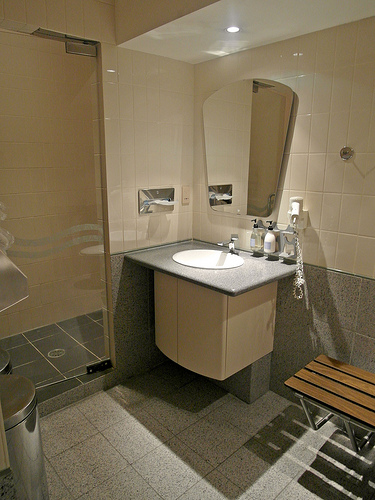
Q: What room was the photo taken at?
A: It was taken at the bathroom.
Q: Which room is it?
A: It is a bathroom.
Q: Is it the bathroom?
A: Yes, it is the bathroom.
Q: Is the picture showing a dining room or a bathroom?
A: It is showing a bathroom.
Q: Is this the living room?
A: No, it is the bathroom.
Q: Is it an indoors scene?
A: Yes, it is indoors.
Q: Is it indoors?
A: Yes, it is indoors.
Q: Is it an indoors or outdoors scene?
A: It is indoors.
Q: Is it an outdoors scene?
A: No, it is indoors.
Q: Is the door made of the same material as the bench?
A: No, the door is made of glass and the bench is made of wood.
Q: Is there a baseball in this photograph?
A: No, there are no baseballs.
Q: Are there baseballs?
A: No, there are no baseballs.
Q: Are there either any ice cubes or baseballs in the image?
A: No, there are no baseballs or ice cubes.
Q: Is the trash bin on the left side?
A: Yes, the trash bin is on the left of the image.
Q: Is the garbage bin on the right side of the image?
A: No, the garbage bin is on the left of the image.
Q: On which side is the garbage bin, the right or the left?
A: The garbage bin is on the left of the image.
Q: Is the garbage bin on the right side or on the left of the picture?
A: The garbage bin is on the left of the image.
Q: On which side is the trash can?
A: The trash can is on the left of the image.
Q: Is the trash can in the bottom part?
A: Yes, the trash can is in the bottom of the image.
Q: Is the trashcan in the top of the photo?
A: No, the trashcan is in the bottom of the image.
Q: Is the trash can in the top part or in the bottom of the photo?
A: The trash can is in the bottom of the image.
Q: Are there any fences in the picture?
A: No, there are no fences.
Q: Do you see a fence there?
A: No, there are no fences.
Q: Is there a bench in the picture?
A: Yes, there is a bench.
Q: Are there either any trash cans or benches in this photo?
A: Yes, there is a bench.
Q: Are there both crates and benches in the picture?
A: No, there is a bench but no crates.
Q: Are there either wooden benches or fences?
A: Yes, there is a wood bench.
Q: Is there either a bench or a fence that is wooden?
A: Yes, the bench is wooden.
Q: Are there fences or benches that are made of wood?
A: Yes, the bench is made of wood.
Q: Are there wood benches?
A: Yes, there is a bench that is made of wood.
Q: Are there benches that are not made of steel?
A: Yes, there is a bench that is made of wood.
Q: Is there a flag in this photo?
A: No, there are no flags.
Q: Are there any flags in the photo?
A: No, there are no flags.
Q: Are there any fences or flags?
A: No, there are no flags or fences.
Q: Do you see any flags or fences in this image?
A: No, there are no flags or fences.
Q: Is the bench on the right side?
A: Yes, the bench is on the right of the image.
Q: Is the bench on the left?
A: No, the bench is on the right of the image.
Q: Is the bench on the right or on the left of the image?
A: The bench is on the right of the image.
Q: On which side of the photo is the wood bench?
A: The bench is on the right of the image.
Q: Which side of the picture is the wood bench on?
A: The bench is on the right of the image.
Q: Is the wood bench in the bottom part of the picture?
A: Yes, the bench is in the bottom of the image.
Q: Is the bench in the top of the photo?
A: No, the bench is in the bottom of the image.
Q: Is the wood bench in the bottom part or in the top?
A: The bench is in the bottom of the image.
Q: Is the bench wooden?
A: Yes, the bench is wooden.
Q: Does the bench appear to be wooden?
A: Yes, the bench is wooden.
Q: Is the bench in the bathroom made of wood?
A: Yes, the bench is made of wood.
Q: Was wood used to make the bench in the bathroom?
A: Yes, the bench is made of wood.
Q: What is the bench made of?
A: The bench is made of wood.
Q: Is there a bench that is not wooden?
A: No, there is a bench but it is wooden.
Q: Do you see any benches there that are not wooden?
A: No, there is a bench but it is wooden.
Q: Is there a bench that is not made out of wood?
A: No, there is a bench but it is made of wood.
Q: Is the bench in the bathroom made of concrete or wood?
A: The bench is made of wood.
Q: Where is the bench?
A: The bench is in the bathroom.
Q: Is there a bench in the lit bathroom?
A: Yes, there is a bench in the bathroom.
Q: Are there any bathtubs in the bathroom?
A: No, there is a bench in the bathroom.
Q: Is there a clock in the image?
A: No, there are no clocks.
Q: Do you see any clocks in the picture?
A: No, there are no clocks.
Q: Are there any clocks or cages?
A: No, there are no clocks or cages.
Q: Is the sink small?
A: Yes, the sink is small.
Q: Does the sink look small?
A: Yes, the sink is small.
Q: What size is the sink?
A: The sink is small.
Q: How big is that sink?
A: The sink is small.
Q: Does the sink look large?
A: No, the sink is small.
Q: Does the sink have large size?
A: No, the sink is small.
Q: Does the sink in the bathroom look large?
A: No, the sink is small.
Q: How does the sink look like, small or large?
A: The sink is small.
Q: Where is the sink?
A: The sink is in the bathroom.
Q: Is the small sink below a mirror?
A: Yes, the sink is below a mirror.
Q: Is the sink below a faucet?
A: No, the sink is below a mirror.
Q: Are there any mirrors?
A: Yes, there is a mirror.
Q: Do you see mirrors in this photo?
A: Yes, there is a mirror.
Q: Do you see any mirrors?
A: Yes, there is a mirror.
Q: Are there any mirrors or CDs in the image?
A: Yes, there is a mirror.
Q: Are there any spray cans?
A: No, there are no spray cans.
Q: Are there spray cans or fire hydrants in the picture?
A: No, there are no spray cans or fire hydrants.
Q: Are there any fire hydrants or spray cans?
A: No, there are no spray cans or fire hydrants.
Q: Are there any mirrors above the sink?
A: Yes, there is a mirror above the sink.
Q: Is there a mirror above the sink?
A: Yes, there is a mirror above the sink.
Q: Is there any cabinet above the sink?
A: No, there is a mirror above the sink.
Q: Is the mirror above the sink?
A: Yes, the mirror is above the sink.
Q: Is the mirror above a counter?
A: No, the mirror is above the sink.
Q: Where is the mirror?
A: The mirror is in the bathroom.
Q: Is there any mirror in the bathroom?
A: Yes, there is a mirror in the bathroom.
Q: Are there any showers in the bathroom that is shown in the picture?
A: No, there is a mirror in the bathroom.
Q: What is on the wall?
A: The mirror is on the wall.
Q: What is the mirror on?
A: The mirror is on the wall.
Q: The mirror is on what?
A: The mirror is on the wall.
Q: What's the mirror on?
A: The mirror is on the wall.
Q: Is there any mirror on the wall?
A: Yes, there is a mirror on the wall.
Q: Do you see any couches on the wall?
A: No, there is a mirror on the wall.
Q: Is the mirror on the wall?
A: Yes, the mirror is on the wall.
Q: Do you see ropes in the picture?
A: No, there are no ropes.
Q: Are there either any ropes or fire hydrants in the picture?
A: No, there are no ropes or fire hydrants.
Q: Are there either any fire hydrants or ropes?
A: No, there are no ropes or fire hydrants.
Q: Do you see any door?
A: Yes, there is a door.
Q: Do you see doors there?
A: Yes, there is a door.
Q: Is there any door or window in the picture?
A: Yes, there is a door.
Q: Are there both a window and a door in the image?
A: No, there is a door but no windows.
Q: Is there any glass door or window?
A: Yes, there is a glass door.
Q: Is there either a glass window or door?
A: Yes, there is a glass door.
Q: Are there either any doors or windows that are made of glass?
A: Yes, the door is made of glass.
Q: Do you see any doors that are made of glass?
A: Yes, there is a door that is made of glass.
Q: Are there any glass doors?
A: Yes, there is a door that is made of glass.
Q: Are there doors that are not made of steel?
A: Yes, there is a door that is made of glass.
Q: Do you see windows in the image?
A: No, there are no windows.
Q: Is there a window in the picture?
A: No, there are no windows.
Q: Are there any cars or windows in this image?
A: No, there are no windows or cars.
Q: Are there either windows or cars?
A: No, there are no windows or cars.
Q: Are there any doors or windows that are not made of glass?
A: No, there is a door but it is made of glass.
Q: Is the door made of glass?
A: Yes, the door is made of glass.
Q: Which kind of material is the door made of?
A: The door is made of glass.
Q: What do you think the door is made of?
A: The door is made of glass.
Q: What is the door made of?
A: The door is made of glass.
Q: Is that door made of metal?
A: No, the door is made of glass.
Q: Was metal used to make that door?
A: No, the door is made of glass.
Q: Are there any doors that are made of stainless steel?
A: No, there is a door but it is made of glass.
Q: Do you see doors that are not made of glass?
A: No, there is a door but it is made of glass.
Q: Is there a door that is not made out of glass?
A: No, there is a door but it is made of glass.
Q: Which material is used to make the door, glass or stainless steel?
A: The door is made of glass.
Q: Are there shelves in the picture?
A: No, there are no shelves.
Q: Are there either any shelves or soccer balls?
A: No, there are no shelves or soccer balls.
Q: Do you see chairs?
A: No, there are no chairs.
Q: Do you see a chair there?
A: No, there are no chairs.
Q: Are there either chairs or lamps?
A: No, there are no chairs or lamps.